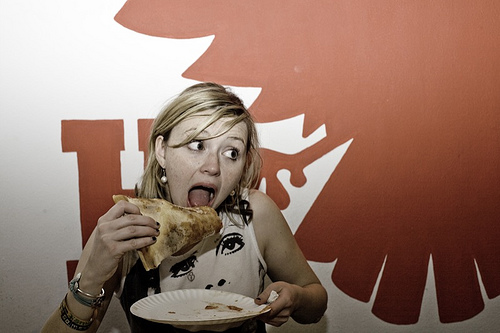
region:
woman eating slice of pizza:
[91, 95, 233, 332]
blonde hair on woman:
[136, 78, 234, 130]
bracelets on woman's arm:
[72, 275, 109, 309]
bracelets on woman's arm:
[56, 308, 83, 325]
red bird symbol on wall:
[232, 9, 491, 264]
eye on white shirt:
[223, 227, 248, 264]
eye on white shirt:
[174, 254, 196, 298]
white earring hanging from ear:
[155, 175, 172, 184]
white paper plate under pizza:
[137, 289, 252, 321]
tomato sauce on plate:
[211, 300, 244, 320]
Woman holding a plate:
[123, 286, 279, 331]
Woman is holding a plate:
[127, 287, 275, 332]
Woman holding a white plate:
[122, 280, 282, 331]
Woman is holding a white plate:
[122, 285, 280, 330]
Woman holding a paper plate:
[123, 282, 276, 330]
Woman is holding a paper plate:
[120, 285, 279, 330]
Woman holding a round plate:
[126, 283, 279, 330]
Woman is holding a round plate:
[124, 283, 284, 331]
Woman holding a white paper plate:
[125, 280, 280, 330]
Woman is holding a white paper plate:
[122, 284, 277, 331]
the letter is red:
[72, 127, 122, 194]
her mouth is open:
[185, 175, 218, 206]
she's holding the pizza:
[123, 203, 170, 243]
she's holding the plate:
[245, 295, 272, 315]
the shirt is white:
[230, 258, 246, 274]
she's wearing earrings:
[156, 165, 167, 183]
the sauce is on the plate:
[225, 303, 241, 313]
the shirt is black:
[126, 280, 139, 292]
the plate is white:
[172, 295, 193, 307]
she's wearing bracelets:
[57, 304, 84, 326]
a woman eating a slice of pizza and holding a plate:
[42, 84, 326, 329]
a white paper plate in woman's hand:
[131, 286, 268, 320]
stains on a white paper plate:
[168, 300, 242, 314]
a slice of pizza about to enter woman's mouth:
[110, 192, 221, 269]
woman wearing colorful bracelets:
[58, 272, 106, 332]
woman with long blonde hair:
[122, 80, 263, 279]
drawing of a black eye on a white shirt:
[215, 230, 245, 252]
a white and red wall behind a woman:
[0, 8, 497, 330]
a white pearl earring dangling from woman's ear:
[160, 166, 168, 184]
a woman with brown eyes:
[187, 140, 237, 160]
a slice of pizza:
[110, 192, 223, 272]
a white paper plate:
[127, 286, 295, 326]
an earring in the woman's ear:
[158, 160, 168, 183]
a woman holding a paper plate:
[35, 81, 328, 331]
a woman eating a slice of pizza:
[38, 81, 328, 331]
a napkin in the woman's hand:
[265, 288, 280, 304]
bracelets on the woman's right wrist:
[57, 272, 105, 332]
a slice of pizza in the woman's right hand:
[72, 193, 223, 272]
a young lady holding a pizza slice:
[39, 81, 330, 331]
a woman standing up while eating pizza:
[35, 72, 342, 332]